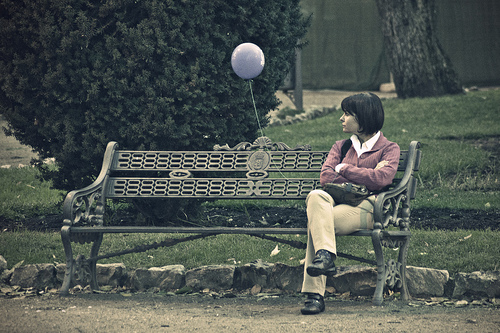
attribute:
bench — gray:
[75, 133, 374, 248]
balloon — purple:
[223, 31, 270, 89]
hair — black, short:
[335, 85, 385, 143]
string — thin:
[246, 83, 276, 150]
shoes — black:
[293, 245, 339, 324]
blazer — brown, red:
[308, 123, 402, 195]